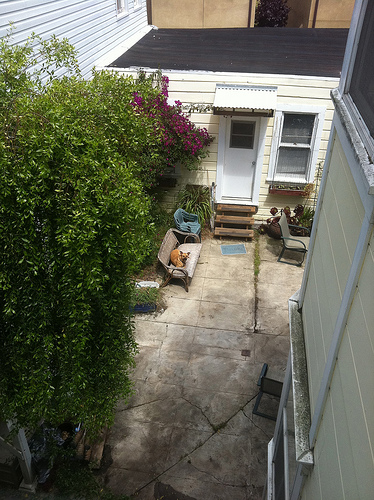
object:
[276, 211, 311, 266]
chair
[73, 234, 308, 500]
concrete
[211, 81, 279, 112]
awning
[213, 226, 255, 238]
steps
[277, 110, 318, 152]
window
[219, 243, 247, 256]
door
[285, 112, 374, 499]
wall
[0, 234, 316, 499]
floor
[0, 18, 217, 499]
tree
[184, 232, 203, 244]
arm chair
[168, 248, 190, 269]
dog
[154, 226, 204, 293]
seat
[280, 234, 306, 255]
arm chair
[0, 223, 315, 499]
ground surface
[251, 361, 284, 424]
chair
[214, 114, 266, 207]
door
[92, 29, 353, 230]
house